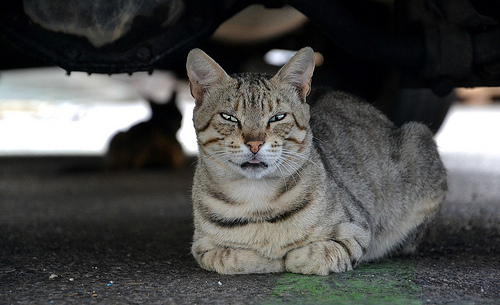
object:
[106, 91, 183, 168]
cat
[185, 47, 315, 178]
head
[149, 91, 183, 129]
head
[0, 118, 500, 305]
ground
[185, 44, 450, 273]
cat fur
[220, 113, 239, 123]
eye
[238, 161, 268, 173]
mouth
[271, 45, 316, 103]
ear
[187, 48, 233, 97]
ear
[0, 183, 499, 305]
asphalt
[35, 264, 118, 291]
debris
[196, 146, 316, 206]
neck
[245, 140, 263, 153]
cat's nose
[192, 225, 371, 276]
legs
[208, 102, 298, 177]
challenging expression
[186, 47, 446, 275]
cat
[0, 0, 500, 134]
car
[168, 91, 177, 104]
ear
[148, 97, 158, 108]
ear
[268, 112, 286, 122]
cat's eye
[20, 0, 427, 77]
undercarriage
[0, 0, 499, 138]
motor vehicle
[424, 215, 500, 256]
shadows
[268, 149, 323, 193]
whiskers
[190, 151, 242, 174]
whiskers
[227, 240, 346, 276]
feet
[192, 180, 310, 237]
stripes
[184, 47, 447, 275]
body